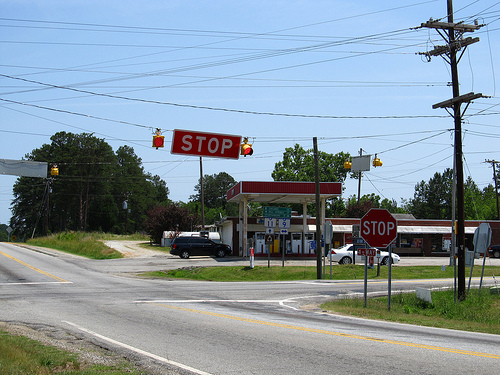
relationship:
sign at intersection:
[358, 207, 399, 249] [253, 276, 500, 361]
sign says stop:
[358, 207, 399, 249] [362, 218, 397, 236]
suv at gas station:
[168, 234, 231, 261] [217, 174, 344, 262]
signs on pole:
[262, 204, 293, 237] [280, 234, 287, 269]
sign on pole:
[358, 207, 399, 249] [385, 244, 395, 315]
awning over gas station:
[225, 179, 344, 206] [217, 174, 344, 262]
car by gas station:
[325, 240, 404, 267] [217, 174, 344, 262]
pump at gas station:
[252, 230, 267, 257] [217, 174, 344, 262]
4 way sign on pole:
[354, 247, 380, 259] [362, 255, 370, 313]